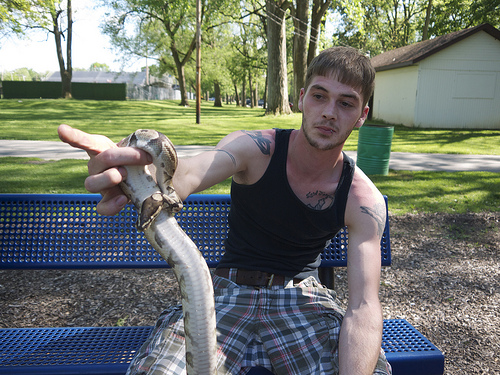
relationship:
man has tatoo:
[58, 47, 398, 374] [303, 189, 338, 210]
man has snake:
[58, 47, 398, 374] [118, 130, 220, 374]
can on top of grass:
[356, 121, 396, 179] [3, 99, 500, 192]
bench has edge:
[1, 191, 446, 374] [2, 351, 447, 374]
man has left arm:
[58, 47, 398, 374] [337, 177, 384, 374]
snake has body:
[118, 130, 220, 374] [116, 130, 219, 373]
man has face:
[58, 47, 398, 374] [298, 46, 374, 153]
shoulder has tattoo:
[220, 126, 289, 194] [238, 128, 272, 156]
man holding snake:
[58, 47, 398, 374] [118, 130, 220, 374]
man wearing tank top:
[58, 47, 398, 374] [217, 128, 354, 285]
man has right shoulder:
[58, 47, 398, 374] [220, 126, 289, 194]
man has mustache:
[58, 47, 398, 374] [312, 120, 344, 133]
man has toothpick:
[58, 47, 398, 374] [329, 128, 336, 136]